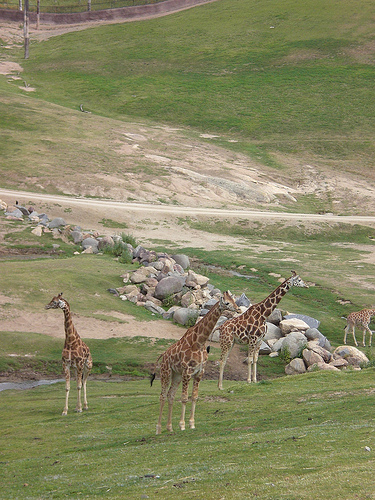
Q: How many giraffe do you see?
A: Four.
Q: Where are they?
A: In the grass.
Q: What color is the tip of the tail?
A: Black.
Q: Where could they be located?
A: Zoo.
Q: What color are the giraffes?
A: Brown.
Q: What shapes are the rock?
A: Round.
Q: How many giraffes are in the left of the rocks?
A: Three.